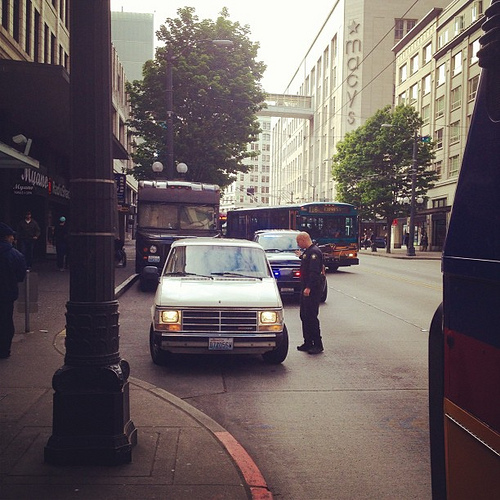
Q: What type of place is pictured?
A: It is a street.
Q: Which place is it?
A: It is a street.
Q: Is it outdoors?
A: Yes, it is outdoors.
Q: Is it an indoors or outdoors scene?
A: It is outdoors.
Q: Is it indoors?
A: No, it is outdoors.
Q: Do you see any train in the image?
A: No, there are no trains.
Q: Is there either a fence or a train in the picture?
A: No, there are no trains or fences.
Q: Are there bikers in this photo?
A: No, there are no bikers.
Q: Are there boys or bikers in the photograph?
A: No, there are no bikers or boys.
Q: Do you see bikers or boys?
A: No, there are no bikers or boys.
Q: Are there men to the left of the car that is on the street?
A: Yes, there is a man to the left of the car.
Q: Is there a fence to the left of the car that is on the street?
A: No, there is a man to the left of the car.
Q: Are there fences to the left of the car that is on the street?
A: No, there is a man to the left of the car.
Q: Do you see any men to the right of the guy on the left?
A: Yes, there is a man to the right of the guy.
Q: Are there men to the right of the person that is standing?
A: Yes, there is a man to the right of the guy.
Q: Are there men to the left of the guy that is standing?
A: No, the man is to the right of the guy.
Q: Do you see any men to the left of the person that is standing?
A: No, the man is to the right of the guy.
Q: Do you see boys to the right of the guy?
A: No, there is a man to the right of the guy.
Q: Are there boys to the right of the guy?
A: No, there is a man to the right of the guy.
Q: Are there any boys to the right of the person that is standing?
A: No, there is a man to the right of the guy.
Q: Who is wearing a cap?
A: The man is wearing a cap.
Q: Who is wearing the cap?
A: The man is wearing a cap.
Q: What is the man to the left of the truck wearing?
A: The man is wearing a cap.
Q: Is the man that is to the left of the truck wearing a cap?
A: Yes, the man is wearing a cap.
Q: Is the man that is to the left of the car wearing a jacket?
A: No, the man is wearing a cap.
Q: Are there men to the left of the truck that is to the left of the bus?
A: Yes, there is a man to the left of the truck.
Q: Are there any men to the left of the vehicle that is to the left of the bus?
A: Yes, there is a man to the left of the truck.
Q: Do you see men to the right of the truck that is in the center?
A: No, the man is to the left of the truck.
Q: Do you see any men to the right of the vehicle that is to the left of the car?
A: No, the man is to the left of the truck.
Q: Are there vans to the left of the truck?
A: No, there is a man to the left of the truck.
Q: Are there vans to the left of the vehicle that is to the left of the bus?
A: No, there is a man to the left of the truck.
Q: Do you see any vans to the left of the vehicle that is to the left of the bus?
A: No, there is a man to the left of the truck.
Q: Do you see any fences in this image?
A: No, there are no fences.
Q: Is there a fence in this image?
A: No, there are no fences.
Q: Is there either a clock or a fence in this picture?
A: No, there are no fences or clocks.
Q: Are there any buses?
A: Yes, there is a bus.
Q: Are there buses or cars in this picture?
A: Yes, there is a bus.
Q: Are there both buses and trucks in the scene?
A: Yes, there are both a bus and a truck.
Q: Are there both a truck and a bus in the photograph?
A: Yes, there are both a bus and a truck.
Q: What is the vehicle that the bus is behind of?
A: The vehicle is a car.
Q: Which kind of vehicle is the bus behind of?
A: The bus is behind the car.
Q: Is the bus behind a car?
A: Yes, the bus is behind a car.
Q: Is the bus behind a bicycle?
A: No, the bus is behind a car.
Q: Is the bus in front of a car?
A: No, the bus is behind a car.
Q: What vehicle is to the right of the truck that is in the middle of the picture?
A: The vehicle is a bus.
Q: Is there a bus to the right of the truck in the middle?
A: Yes, there is a bus to the right of the truck.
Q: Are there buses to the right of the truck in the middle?
A: Yes, there is a bus to the right of the truck.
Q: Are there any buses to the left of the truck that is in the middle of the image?
A: No, the bus is to the right of the truck.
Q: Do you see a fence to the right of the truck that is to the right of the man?
A: No, there is a bus to the right of the truck.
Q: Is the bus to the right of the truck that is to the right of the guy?
A: Yes, the bus is to the right of the truck.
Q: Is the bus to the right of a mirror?
A: No, the bus is to the right of the truck.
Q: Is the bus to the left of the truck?
A: No, the bus is to the right of the truck.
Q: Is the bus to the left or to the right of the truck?
A: The bus is to the right of the truck.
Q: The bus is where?
A: The bus is on the street.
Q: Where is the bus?
A: The bus is on the street.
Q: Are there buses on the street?
A: Yes, there is a bus on the street.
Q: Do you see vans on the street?
A: No, there is a bus on the street.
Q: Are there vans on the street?
A: No, there is a bus on the street.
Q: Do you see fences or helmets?
A: No, there are no fences or helmets.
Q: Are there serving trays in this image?
A: No, there are no serving trays.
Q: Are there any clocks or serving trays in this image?
A: No, there are no serving trays or clocks.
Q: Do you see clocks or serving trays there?
A: No, there are no serving trays or clocks.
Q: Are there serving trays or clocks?
A: No, there are no serving trays or clocks.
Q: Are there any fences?
A: No, there are no fences.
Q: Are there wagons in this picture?
A: No, there are no wagons.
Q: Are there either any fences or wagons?
A: No, there are no wagons or fences.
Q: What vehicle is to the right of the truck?
A: The vehicle is a car.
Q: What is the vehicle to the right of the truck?
A: The vehicle is a car.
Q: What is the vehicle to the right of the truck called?
A: The vehicle is a car.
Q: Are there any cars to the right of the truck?
A: Yes, there is a car to the right of the truck.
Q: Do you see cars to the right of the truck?
A: Yes, there is a car to the right of the truck.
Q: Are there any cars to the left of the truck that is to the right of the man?
A: No, the car is to the right of the truck.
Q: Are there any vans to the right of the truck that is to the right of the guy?
A: No, there is a car to the right of the truck.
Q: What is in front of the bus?
A: The car is in front of the bus.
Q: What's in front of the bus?
A: The car is in front of the bus.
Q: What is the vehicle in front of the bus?
A: The vehicle is a car.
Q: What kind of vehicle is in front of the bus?
A: The vehicle is a car.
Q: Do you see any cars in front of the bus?
A: Yes, there is a car in front of the bus.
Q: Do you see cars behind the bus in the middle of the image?
A: No, the car is in front of the bus.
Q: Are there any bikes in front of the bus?
A: No, there is a car in front of the bus.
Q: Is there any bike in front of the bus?
A: No, there is a car in front of the bus.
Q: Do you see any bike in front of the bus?
A: No, there is a car in front of the bus.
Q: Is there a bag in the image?
A: No, there are no bags.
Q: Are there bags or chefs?
A: No, there are no bags or chefs.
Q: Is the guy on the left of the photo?
A: Yes, the guy is on the left of the image.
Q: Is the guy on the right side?
A: No, the guy is on the left of the image.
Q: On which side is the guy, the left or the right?
A: The guy is on the left of the image.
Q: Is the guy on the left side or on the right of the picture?
A: The guy is on the left of the image.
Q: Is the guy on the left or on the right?
A: The guy is on the left of the image.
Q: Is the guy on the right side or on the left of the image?
A: The guy is on the left of the image.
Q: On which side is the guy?
A: The guy is on the left of the image.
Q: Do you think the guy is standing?
A: Yes, the guy is standing.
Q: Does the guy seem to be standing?
A: Yes, the guy is standing.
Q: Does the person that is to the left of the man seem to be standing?
A: Yes, the guy is standing.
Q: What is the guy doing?
A: The guy is standing.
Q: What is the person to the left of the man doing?
A: The guy is standing.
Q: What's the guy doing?
A: The guy is standing.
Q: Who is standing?
A: The guy is standing.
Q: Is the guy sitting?
A: No, the guy is standing.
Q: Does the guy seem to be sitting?
A: No, the guy is standing.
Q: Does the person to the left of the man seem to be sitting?
A: No, the guy is standing.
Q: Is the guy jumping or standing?
A: The guy is standing.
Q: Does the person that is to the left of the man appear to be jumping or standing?
A: The guy is standing.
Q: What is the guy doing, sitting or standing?
A: The guy is standing.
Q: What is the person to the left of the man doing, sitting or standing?
A: The guy is standing.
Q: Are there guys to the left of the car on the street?
A: Yes, there is a guy to the left of the car.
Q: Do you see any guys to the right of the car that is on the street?
A: No, the guy is to the left of the car.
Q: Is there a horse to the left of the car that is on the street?
A: No, there is a guy to the left of the car.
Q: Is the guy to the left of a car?
A: Yes, the guy is to the left of a car.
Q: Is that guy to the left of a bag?
A: No, the guy is to the left of a car.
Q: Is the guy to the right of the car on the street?
A: No, the guy is to the left of the car.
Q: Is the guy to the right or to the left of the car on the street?
A: The guy is to the left of the car.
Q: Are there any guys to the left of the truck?
A: Yes, there is a guy to the left of the truck.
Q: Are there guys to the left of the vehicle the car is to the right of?
A: Yes, there is a guy to the left of the truck.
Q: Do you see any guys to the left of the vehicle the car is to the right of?
A: Yes, there is a guy to the left of the truck.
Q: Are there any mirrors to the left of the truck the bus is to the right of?
A: No, there is a guy to the left of the truck.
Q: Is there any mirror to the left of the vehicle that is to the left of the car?
A: No, there is a guy to the left of the truck.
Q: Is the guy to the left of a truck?
A: Yes, the guy is to the left of a truck.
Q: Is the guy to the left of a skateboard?
A: No, the guy is to the left of a truck.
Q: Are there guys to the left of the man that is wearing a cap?
A: Yes, there is a guy to the left of the man.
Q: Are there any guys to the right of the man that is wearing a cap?
A: No, the guy is to the left of the man.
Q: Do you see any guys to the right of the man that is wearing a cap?
A: No, the guy is to the left of the man.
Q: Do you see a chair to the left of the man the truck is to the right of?
A: No, there is a guy to the left of the man.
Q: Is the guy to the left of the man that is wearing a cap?
A: Yes, the guy is to the left of the man.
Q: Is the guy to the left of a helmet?
A: No, the guy is to the left of the man.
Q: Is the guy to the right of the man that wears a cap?
A: No, the guy is to the left of the man.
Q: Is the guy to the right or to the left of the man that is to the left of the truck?
A: The guy is to the left of the man.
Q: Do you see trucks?
A: Yes, there is a truck.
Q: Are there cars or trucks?
A: Yes, there is a truck.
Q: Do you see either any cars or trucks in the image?
A: Yes, there is a truck.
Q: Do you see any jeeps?
A: No, there are no jeeps.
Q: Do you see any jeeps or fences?
A: No, there are no jeeps or fences.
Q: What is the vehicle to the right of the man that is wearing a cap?
A: The vehicle is a truck.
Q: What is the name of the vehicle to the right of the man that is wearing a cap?
A: The vehicle is a truck.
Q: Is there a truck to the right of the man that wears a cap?
A: Yes, there is a truck to the right of the man.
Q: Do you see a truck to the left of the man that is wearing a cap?
A: No, the truck is to the right of the man.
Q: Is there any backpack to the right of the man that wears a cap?
A: No, there is a truck to the right of the man.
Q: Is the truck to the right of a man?
A: Yes, the truck is to the right of a man.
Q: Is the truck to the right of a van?
A: No, the truck is to the right of a man.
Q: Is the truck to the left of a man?
A: No, the truck is to the right of a man.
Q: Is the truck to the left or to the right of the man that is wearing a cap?
A: The truck is to the right of the man.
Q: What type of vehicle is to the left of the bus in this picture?
A: The vehicle is a truck.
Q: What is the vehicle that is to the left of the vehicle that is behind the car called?
A: The vehicle is a truck.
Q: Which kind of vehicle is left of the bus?
A: The vehicle is a truck.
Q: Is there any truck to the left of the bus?
A: Yes, there is a truck to the left of the bus.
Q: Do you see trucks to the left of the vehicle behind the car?
A: Yes, there is a truck to the left of the bus.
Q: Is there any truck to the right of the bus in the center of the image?
A: No, the truck is to the left of the bus.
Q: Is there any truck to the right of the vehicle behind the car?
A: No, the truck is to the left of the bus.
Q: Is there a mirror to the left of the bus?
A: No, there is a truck to the left of the bus.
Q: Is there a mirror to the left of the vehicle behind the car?
A: No, there is a truck to the left of the bus.